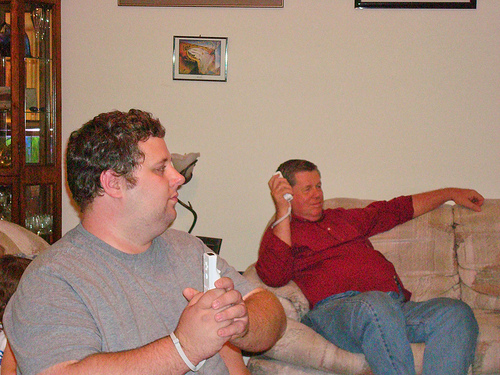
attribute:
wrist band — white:
[171, 333, 204, 370]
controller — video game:
[196, 242, 222, 294]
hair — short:
[273, 151, 307, 188]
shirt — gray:
[2, 224, 259, 372]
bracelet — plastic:
[164, 328, 206, 372]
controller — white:
[264, 163, 301, 212]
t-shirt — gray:
[1, 228, 269, 373]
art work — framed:
[170, 31, 254, 94]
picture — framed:
[168, 32, 231, 84]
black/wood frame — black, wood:
[351, 0, 479, 12]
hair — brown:
[60, 105, 173, 212]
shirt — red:
[247, 192, 416, 305]